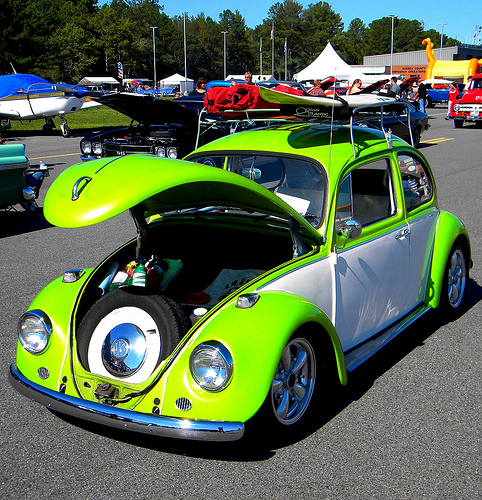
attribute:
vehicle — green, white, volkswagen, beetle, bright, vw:
[8, 120, 474, 446]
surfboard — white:
[256, 84, 396, 109]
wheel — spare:
[78, 282, 181, 388]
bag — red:
[201, 84, 228, 111]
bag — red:
[228, 80, 302, 110]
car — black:
[81, 84, 266, 159]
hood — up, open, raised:
[90, 92, 197, 125]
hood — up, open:
[41, 151, 325, 239]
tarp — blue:
[0, 71, 89, 98]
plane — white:
[1, 59, 90, 137]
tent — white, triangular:
[289, 38, 365, 84]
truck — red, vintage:
[448, 70, 480, 125]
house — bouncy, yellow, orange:
[416, 38, 481, 87]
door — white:
[332, 222, 427, 351]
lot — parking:
[0, 111, 481, 498]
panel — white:
[256, 258, 335, 324]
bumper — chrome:
[6, 362, 244, 446]